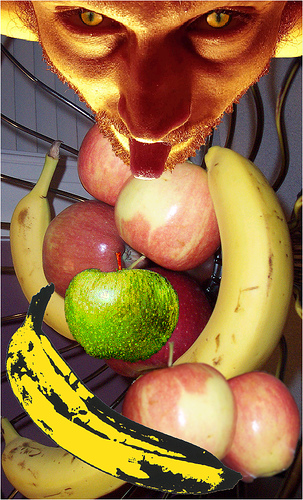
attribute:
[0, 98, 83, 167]
bar — black  , metal   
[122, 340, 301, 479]
apples — red, yellow 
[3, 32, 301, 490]
fruit holder — shiny , silver 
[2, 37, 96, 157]
panels — white 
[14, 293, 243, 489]
banana — cartoon, photoshopped, graphic, colored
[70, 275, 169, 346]
apple — granny smith, green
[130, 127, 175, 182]
tongue — out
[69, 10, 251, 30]
eyes — yellow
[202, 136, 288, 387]
banana — yellow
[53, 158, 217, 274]
apples — red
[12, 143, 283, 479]
fruits — assorted, arranged , pile 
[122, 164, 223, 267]
apple — red, yellow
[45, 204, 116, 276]
apple — red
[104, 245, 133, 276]
stem — red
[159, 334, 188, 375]
stem — green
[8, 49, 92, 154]
paneling — grey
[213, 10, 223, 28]
pupils — cat like